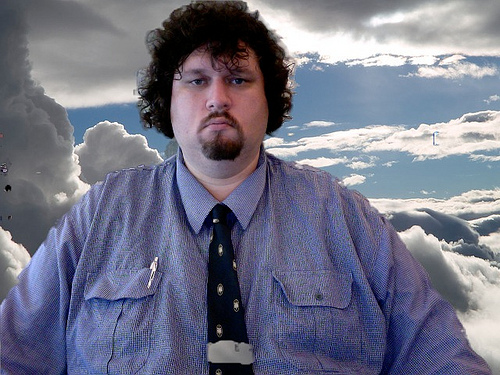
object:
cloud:
[332, 5, 441, 63]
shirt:
[0, 144, 493, 374]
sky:
[53, 99, 114, 138]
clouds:
[390, 109, 475, 166]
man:
[0, 1, 491, 375]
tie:
[206, 202, 255, 374]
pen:
[139, 252, 166, 291]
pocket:
[69, 265, 168, 364]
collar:
[173, 153, 278, 234]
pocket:
[272, 267, 359, 365]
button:
[310, 285, 330, 299]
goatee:
[189, 112, 245, 163]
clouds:
[328, 129, 377, 170]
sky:
[298, 72, 362, 126]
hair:
[143, 0, 285, 65]